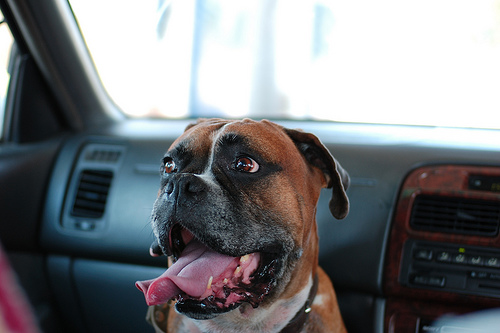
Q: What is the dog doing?
A: Panting.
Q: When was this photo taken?
A: During the day.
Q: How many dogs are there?
A: One.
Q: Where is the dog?
A: In the car.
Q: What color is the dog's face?
A: Black.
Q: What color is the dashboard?
A: Black.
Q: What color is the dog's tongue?
A: Pink.